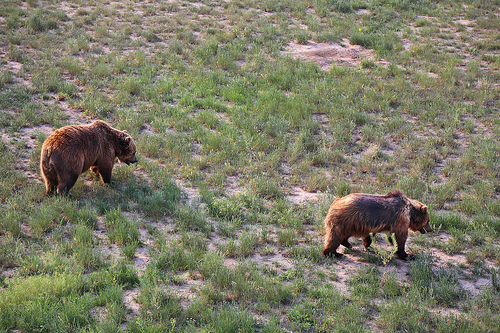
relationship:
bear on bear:
[41, 120, 138, 197] [38, 117, 138, 194]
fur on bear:
[346, 200, 378, 220] [310, 185, 435, 266]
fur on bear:
[351, 192, 388, 224] [240, 150, 474, 264]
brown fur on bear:
[64, 132, 106, 154] [50, 113, 160, 190]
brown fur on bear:
[60, 128, 88, 154] [29, 114, 141, 199]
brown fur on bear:
[67, 135, 95, 155] [299, 157, 447, 264]